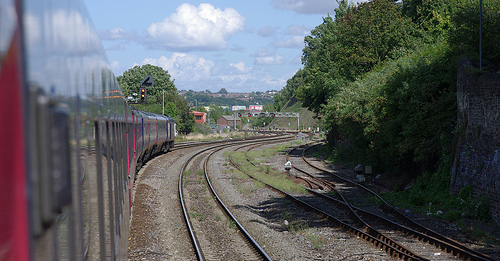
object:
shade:
[232, 196, 353, 231]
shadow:
[235, 142, 453, 244]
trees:
[254, 4, 497, 119]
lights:
[135, 85, 148, 105]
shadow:
[232, 197, 358, 234]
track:
[174, 132, 297, 259]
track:
[230, 135, 484, 259]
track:
[285, 141, 476, 259]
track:
[173, 132, 244, 152]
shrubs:
[275, 0, 499, 224]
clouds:
[84, 3, 372, 98]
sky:
[79, 2, 268, 114]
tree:
[369, 0, 462, 170]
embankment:
[352, 145, 490, 201]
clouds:
[112, 10, 243, 50]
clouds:
[141, 55, 236, 82]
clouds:
[253, 50, 285, 67]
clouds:
[273, 0, 336, 16]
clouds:
[100, 28, 137, 53]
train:
[0, 4, 175, 259]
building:
[192, 106, 209, 126]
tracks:
[169, 181, 373, 258]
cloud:
[147, 3, 244, 50]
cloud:
[250, 50, 284, 72]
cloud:
[98, 18, 133, 50]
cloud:
[220, 57, 251, 78]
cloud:
[141, 48, 215, 86]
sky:
[81, 3, 338, 63]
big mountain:
[182, 83, 259, 100]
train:
[0, 37, 438, 256]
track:
[119, 110, 382, 258]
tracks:
[144, 98, 495, 259]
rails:
[182, 149, 319, 259]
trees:
[288, 0, 455, 58]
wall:
[440, 15, 499, 222]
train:
[69, 26, 186, 182]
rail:
[149, 130, 427, 259]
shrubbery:
[331, 34, 466, 179]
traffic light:
[123, 64, 172, 170]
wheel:
[160, 141, 170, 152]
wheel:
[150, 144, 158, 156]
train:
[22, 117, 119, 198]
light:
[137, 87, 147, 104]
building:
[218, 108, 245, 130]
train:
[83, 102, 182, 152]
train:
[110, 103, 182, 150]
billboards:
[207, 97, 275, 115]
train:
[1, 3, 194, 258]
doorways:
[119, 107, 164, 166]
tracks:
[173, 128, 276, 151]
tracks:
[229, 117, 470, 259]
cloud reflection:
[33, 10, 108, 80]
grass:
[238, 140, 329, 219]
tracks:
[228, 127, 403, 188]